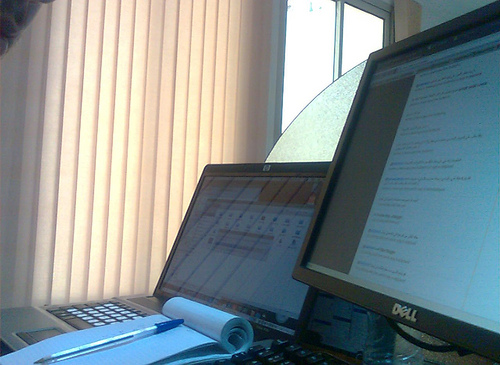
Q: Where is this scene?
A: An office.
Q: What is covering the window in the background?
A: Blinds.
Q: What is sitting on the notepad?
A: A pen.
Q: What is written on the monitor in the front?
A: Dell.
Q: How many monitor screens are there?
A: Two.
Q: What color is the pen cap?
A: Blue.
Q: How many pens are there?
A: One.